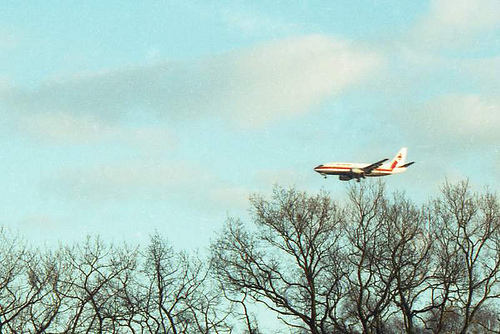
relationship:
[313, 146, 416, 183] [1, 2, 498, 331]
airplane in air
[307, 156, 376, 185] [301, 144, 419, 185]
line on plane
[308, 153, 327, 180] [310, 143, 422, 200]
tip of plane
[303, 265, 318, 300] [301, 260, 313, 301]
part of branch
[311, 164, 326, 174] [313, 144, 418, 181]
nose tip of plane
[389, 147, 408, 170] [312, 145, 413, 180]
tail of plane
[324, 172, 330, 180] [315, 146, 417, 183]
front wheel of plane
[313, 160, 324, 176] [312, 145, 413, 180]
nose of plane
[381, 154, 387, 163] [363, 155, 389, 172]
tip of wing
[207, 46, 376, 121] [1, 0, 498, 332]
clouds in air